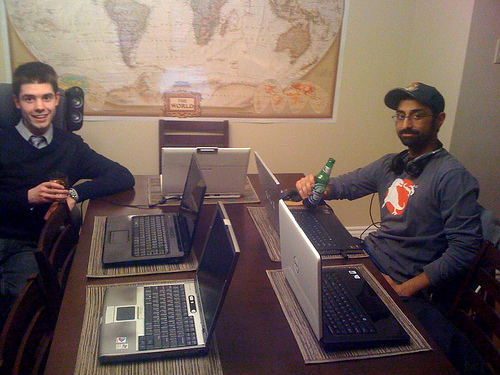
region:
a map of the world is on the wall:
[6, 1, 341, 120]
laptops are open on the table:
[86, 140, 411, 360]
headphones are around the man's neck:
[376, 135, 453, 184]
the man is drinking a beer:
[294, 82, 451, 219]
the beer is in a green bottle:
[301, 152, 337, 212]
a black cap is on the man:
[384, 78, 446, 120]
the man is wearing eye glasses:
[389, 105, 435, 125]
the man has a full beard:
[386, 90, 440, 154]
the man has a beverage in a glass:
[43, 174, 71, 204]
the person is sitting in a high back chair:
[3, 57, 88, 274]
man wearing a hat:
[372, 77, 450, 164]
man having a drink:
[0, 62, 128, 238]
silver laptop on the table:
[87, 199, 253, 366]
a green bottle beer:
[292, 157, 348, 207]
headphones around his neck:
[377, 140, 454, 185]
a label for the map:
[156, 87, 206, 115]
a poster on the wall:
[2, 0, 355, 117]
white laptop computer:
[158, 133, 252, 201]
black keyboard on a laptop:
[102, 212, 189, 264]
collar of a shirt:
[12, 115, 62, 152]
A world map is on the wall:
[3, 0, 353, 126]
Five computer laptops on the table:
[90, 132, 417, 374]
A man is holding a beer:
[293, 148, 344, 214]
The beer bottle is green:
[290, 143, 346, 220]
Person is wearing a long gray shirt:
[311, 131, 487, 311]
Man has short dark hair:
[3, 58, 77, 143]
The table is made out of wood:
[43, 158, 459, 372]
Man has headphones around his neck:
[377, 132, 453, 187]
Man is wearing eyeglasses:
[375, 100, 446, 135]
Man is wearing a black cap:
[369, 63, 464, 135]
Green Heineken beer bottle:
[297, 151, 339, 215]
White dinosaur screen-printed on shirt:
[375, 166, 420, 218]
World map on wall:
[1, 0, 346, 121]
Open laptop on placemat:
[270, 195, 415, 350]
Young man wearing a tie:
[0, 56, 135, 306]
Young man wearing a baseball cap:
[295, 80, 485, 300]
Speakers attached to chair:
[57, 82, 87, 132]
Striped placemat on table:
[70, 277, 220, 372]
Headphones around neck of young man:
[381, 135, 447, 175]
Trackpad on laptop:
[101, 303, 144, 324]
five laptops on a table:
[104, 140, 373, 371]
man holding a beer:
[297, 136, 355, 221]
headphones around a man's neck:
[386, 142, 459, 179]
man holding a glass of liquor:
[41, 165, 79, 205]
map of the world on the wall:
[28, 2, 339, 112]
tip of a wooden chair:
[155, 119, 237, 146]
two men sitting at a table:
[14, 55, 471, 275]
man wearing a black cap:
[376, 65, 445, 112]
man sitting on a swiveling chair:
[0, 62, 82, 264]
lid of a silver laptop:
[166, 148, 249, 195]